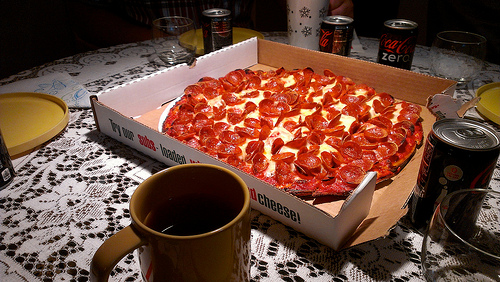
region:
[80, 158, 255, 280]
a brown coffee mug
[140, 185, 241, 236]
liquid in the cup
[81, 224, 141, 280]
the handle of a mug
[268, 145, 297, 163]
a piece of pepperoni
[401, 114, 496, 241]
a metal can on the table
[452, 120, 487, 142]
a metal pop top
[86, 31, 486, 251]
a cardboard box on the table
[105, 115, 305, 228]
writing on the box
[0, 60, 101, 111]
a napkin on the table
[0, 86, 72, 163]
a yellow plastic lid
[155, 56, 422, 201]
Pepperoni pizza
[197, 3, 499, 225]
Four beverage cans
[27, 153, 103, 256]
White laced table cloth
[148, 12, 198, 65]
Glass for drinks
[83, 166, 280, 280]
Brown coffee mug on the table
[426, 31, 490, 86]
Glass with ice cubes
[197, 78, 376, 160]
Red pepperoni on pizza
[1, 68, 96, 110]
paper napkin on the table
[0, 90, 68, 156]
Yellow plate on the table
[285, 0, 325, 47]
Plastic glass with snowflakes design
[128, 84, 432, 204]
a pizza in a box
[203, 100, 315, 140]
slices of pepperoni on a pizza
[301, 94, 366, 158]
melted cheese on a pizza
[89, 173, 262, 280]
a brown coffee cup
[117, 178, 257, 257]
coffee in a coffee cup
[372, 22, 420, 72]
a drink can on a table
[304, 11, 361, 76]
a drink can next to a pizza box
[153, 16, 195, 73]
a clear glass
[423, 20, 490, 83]
a glass with ice in it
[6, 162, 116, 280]
white lace tablecloth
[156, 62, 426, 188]
Extra Pepperoni and cheese pizza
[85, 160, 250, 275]
Yellow mug of coffee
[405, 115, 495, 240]
Unopened can of Coke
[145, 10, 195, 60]
Empty glass drinking cup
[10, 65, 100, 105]
Folded up paper towel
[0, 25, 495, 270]
White floral table cloth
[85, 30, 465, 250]
Box of pepperoni pizza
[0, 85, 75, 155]
Empty plastic yellow plate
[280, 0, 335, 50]
White patterned coffee mug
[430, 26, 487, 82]
Clear Drinking glass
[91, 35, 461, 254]
A pizza box.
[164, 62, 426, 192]
A large pizza.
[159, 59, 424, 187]
A pizza covered in pepperoni slices.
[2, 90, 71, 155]
A yellow plate.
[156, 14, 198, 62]
A small clear glass.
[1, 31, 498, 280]
A white laced tablecloth.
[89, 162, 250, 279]
A yellow coffee mug.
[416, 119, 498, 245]
A can of soda.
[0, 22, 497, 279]
A round table.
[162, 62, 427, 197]
A pepperoni and cheese pizza.